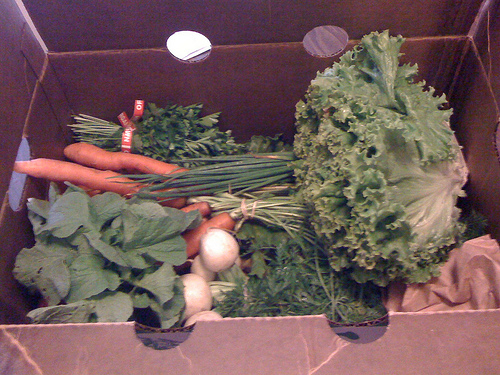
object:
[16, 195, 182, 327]
kales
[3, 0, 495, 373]
brown box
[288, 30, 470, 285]
vegetables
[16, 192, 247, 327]
vegetables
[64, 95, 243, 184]
vegetables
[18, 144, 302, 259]
vegetables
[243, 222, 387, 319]
vegetables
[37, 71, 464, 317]
vegetables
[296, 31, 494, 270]
cabbage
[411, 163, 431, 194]
ground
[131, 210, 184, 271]
kale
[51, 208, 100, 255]
kale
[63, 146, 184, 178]
carrot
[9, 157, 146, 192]
carrot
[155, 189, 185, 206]
carrot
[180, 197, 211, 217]
carrot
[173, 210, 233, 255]
carrot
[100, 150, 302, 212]
green onions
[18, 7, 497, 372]
table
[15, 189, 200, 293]
leaves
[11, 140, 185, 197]
carrots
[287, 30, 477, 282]
lettuce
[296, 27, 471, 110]
head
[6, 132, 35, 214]
handhold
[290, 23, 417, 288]
leaves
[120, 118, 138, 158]
lettering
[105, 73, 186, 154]
label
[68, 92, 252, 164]
produce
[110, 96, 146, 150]
band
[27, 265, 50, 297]
caterpillar holes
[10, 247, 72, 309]
leaf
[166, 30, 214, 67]
hole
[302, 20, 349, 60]
hole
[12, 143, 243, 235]
carrots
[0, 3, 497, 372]
box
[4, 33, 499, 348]
box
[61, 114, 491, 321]
vegetables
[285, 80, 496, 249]
lettuce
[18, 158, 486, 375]
box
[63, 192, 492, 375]
vegetables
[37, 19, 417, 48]
surface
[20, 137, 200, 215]
skin